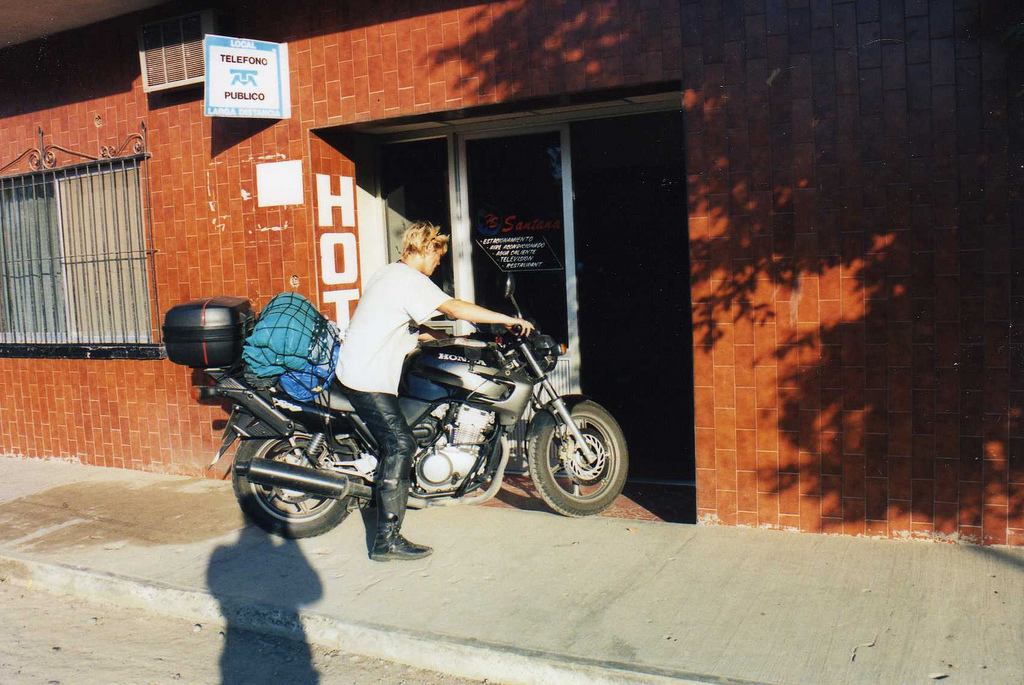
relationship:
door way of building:
[339, 123, 691, 510] [4, 0, 1023, 523]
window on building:
[4, 124, 167, 358] [4, 0, 1023, 523]